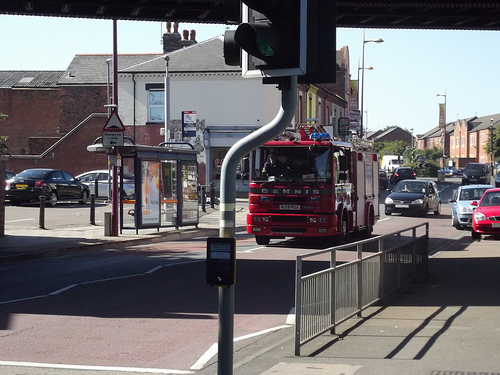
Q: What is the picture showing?
A: It is showing a road.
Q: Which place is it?
A: It is a road.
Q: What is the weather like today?
A: It is cloudless.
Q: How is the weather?
A: It is cloudless.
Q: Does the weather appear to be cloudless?
A: Yes, it is cloudless.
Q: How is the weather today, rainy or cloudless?
A: It is cloudless.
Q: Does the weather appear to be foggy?
A: No, it is cloudless.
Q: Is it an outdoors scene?
A: Yes, it is outdoors.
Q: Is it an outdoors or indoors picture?
A: It is outdoors.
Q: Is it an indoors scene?
A: No, it is outdoors.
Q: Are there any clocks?
A: No, there are no clocks.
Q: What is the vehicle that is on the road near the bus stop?
A: The vehicle is a car.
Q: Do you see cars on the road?
A: Yes, there is a car on the road.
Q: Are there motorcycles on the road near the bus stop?
A: No, there is a car on the road.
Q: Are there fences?
A: Yes, there is a fence.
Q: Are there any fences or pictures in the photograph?
A: Yes, there is a fence.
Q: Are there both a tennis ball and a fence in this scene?
A: No, there is a fence but no tennis balls.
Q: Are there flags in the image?
A: No, there are no flags.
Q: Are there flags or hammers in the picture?
A: No, there are no flags or hammers.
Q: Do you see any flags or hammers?
A: No, there are no flags or hammers.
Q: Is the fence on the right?
A: Yes, the fence is on the right of the image.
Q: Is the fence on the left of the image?
A: No, the fence is on the right of the image.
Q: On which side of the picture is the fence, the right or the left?
A: The fence is on the right of the image.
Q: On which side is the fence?
A: The fence is on the right of the image.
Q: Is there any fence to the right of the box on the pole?
A: Yes, there is a fence to the right of the box.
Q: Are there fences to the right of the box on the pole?
A: Yes, there is a fence to the right of the box.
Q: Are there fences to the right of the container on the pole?
A: Yes, there is a fence to the right of the box.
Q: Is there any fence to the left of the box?
A: No, the fence is to the right of the box.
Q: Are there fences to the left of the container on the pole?
A: No, the fence is to the right of the box.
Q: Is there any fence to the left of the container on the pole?
A: No, the fence is to the right of the box.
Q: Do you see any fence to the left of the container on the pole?
A: No, the fence is to the right of the box.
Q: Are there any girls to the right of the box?
A: No, there is a fence to the right of the box.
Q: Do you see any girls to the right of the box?
A: No, there is a fence to the right of the box.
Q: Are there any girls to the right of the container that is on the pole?
A: No, there is a fence to the right of the box.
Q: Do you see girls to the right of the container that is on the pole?
A: No, there is a fence to the right of the box.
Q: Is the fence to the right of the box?
A: Yes, the fence is to the right of the box.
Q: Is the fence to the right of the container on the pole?
A: Yes, the fence is to the right of the box.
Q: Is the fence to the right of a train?
A: No, the fence is to the right of the box.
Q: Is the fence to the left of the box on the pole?
A: No, the fence is to the right of the box.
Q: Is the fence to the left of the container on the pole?
A: No, the fence is to the right of the box.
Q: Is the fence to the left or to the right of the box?
A: The fence is to the right of the box.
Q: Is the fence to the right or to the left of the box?
A: The fence is to the right of the box.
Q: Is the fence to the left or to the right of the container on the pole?
A: The fence is to the right of the box.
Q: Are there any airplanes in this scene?
A: No, there are no airplanes.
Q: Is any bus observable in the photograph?
A: Yes, there is a bus.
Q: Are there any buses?
A: Yes, there is a bus.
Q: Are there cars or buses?
A: Yes, there is a bus.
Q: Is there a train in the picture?
A: No, there are no trains.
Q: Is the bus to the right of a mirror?
A: No, the bus is to the right of the car.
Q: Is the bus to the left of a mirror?
A: No, the bus is to the left of a car.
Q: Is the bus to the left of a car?
A: Yes, the bus is to the left of a car.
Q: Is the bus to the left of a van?
A: No, the bus is to the left of a car.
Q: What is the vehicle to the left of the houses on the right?
A: The vehicle is a bus.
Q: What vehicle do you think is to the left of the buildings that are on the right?
A: The vehicle is a bus.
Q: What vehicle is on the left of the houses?
A: The vehicle is a bus.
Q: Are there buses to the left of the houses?
A: Yes, there is a bus to the left of the houses.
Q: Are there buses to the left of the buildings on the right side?
A: Yes, there is a bus to the left of the houses.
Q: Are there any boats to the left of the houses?
A: No, there is a bus to the left of the houses.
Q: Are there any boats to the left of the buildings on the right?
A: No, there is a bus to the left of the houses.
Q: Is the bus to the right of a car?
A: Yes, the bus is to the right of a car.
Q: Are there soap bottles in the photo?
A: No, there are no soap bottles.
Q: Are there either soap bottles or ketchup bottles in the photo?
A: No, there are no soap bottles or ketchup bottles.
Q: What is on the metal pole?
A: The box is on the pole.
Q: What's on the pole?
A: The box is on the pole.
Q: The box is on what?
A: The box is on the pole.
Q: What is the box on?
A: The box is on the pole.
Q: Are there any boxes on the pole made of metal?
A: Yes, there is a box on the pole.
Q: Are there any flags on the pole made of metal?
A: No, there is a box on the pole.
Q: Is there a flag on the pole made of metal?
A: No, there is a box on the pole.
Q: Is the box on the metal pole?
A: Yes, the box is on the pole.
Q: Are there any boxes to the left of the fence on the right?
A: Yes, there is a box to the left of the fence.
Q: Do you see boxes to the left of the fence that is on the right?
A: Yes, there is a box to the left of the fence.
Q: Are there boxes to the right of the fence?
A: No, the box is to the left of the fence.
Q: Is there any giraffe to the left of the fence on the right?
A: No, there is a box to the left of the fence.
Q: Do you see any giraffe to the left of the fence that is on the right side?
A: No, there is a box to the left of the fence.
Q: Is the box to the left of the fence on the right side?
A: Yes, the box is to the left of the fence.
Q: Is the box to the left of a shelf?
A: No, the box is to the left of the fence.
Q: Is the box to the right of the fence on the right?
A: No, the box is to the left of the fence.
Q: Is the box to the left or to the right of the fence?
A: The box is to the left of the fence.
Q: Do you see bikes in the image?
A: No, there are no bikes.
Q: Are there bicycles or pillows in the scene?
A: No, there are no bicycles or pillows.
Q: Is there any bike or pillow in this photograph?
A: No, there are no bikes or pillows.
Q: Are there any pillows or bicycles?
A: No, there are no bicycles or pillows.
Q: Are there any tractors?
A: No, there are no tractors.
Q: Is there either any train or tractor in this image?
A: No, there are no tractors or trains.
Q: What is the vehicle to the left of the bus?
A: The vehicle is a car.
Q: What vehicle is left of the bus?
A: The vehicle is a car.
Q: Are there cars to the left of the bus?
A: Yes, there is a car to the left of the bus.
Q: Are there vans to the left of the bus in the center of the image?
A: No, there is a car to the left of the bus.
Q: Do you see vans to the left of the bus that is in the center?
A: No, there is a car to the left of the bus.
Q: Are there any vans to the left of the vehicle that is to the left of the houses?
A: No, there is a car to the left of the bus.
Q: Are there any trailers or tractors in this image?
A: No, there are no tractors or trailers.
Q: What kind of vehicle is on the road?
A: The vehicle is a car.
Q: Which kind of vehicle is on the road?
A: The vehicle is a car.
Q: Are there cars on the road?
A: Yes, there is a car on the road.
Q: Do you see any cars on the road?
A: Yes, there is a car on the road.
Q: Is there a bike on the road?
A: No, there is a car on the road.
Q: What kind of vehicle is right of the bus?
A: The vehicle is a car.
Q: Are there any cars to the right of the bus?
A: Yes, there is a car to the right of the bus.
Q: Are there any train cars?
A: No, there are no train cars.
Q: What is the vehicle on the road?
A: The vehicle is a car.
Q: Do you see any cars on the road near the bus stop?
A: Yes, there is a car on the road.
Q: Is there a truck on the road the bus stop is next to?
A: No, there is a car on the road.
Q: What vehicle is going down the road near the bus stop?
A: The vehicle is a car.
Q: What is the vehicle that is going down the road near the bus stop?
A: The vehicle is a car.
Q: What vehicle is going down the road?
A: The vehicle is a car.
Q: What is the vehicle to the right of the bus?
A: The vehicle is a car.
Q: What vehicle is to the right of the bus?
A: The vehicle is a car.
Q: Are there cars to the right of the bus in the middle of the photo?
A: Yes, there is a car to the right of the bus.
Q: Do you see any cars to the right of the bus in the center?
A: Yes, there is a car to the right of the bus.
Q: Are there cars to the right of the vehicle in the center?
A: Yes, there is a car to the right of the bus.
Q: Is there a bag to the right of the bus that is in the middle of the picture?
A: No, there is a car to the right of the bus.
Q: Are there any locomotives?
A: No, there are no locomotives.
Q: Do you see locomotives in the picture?
A: No, there are no locomotives.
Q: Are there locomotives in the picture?
A: No, there are no locomotives.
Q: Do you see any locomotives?
A: No, there are no locomotives.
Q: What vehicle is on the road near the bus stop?
A: The vehicle is a car.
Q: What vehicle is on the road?
A: The vehicle is a car.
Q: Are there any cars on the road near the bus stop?
A: Yes, there is a car on the road.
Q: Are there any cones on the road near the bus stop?
A: No, there is a car on the road.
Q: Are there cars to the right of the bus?
A: Yes, there is a car to the right of the bus.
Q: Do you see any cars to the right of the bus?
A: Yes, there is a car to the right of the bus.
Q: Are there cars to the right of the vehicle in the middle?
A: Yes, there is a car to the right of the bus.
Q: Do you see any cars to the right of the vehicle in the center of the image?
A: Yes, there is a car to the right of the bus.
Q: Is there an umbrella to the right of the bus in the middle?
A: No, there is a car to the right of the bus.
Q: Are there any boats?
A: No, there are no boats.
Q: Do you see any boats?
A: No, there are no boats.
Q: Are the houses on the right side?
A: Yes, the houses are on the right of the image.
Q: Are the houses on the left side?
A: No, the houses are on the right of the image.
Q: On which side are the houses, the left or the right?
A: The houses are on the right of the image.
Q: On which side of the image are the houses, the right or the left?
A: The houses are on the right of the image.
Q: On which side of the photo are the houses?
A: The houses are on the right of the image.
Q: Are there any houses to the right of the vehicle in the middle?
A: Yes, there are houses to the right of the bus.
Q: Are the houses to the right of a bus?
A: Yes, the houses are to the right of a bus.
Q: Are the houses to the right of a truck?
A: No, the houses are to the right of a bus.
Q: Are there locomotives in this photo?
A: No, there are no locomotives.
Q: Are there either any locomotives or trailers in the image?
A: No, there are no locomotives or trailers.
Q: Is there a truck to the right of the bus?
A: No, there is a car to the right of the bus.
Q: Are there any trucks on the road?
A: No, there is a car on the road.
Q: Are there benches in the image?
A: No, there are no benches.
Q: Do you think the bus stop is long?
A: Yes, the bus stop is long.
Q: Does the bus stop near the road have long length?
A: Yes, the bus stop is long.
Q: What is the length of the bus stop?
A: The bus stop is long.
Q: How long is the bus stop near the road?
A: The bus stop is long.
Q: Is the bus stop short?
A: No, the bus stop is long.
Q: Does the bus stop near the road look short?
A: No, the bus stop is long.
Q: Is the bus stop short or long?
A: The bus stop is long.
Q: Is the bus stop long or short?
A: The bus stop is long.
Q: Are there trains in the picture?
A: No, there are no trains.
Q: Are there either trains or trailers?
A: No, there are no trains or trailers.